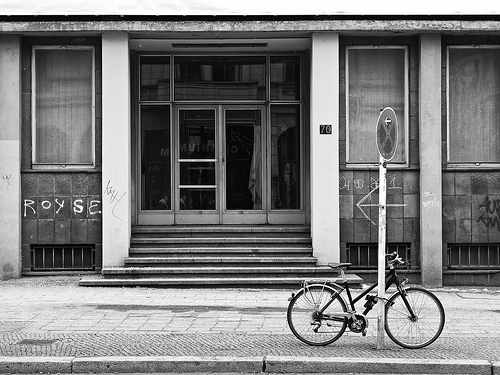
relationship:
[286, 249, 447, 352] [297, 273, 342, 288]
bike has cargo rack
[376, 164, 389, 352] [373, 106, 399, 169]
post has sign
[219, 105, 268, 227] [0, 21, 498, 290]
office door on building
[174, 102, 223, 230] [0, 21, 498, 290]
office door on building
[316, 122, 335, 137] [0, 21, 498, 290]
address numerals are on building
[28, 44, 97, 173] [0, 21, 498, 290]
window on building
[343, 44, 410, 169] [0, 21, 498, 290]
window on building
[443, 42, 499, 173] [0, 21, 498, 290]
window on building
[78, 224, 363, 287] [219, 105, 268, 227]
stairs are near office door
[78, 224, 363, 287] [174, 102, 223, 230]
stairs are near office door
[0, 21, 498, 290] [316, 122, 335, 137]
building has address numerals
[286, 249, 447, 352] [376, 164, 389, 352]
bike attached to post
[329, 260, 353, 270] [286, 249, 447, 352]
seat on bike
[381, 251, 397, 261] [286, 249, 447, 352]
handlebar on bike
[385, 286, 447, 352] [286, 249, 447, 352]
front wheel on bike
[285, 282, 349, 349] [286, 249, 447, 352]
back wheel on bike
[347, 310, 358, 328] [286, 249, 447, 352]
pedal on bike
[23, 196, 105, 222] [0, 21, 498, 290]
grafitti on building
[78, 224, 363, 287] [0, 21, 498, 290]
stairs are going up to building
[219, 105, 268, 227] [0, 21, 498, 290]
office door on front of building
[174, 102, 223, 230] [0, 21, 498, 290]
office door on front of building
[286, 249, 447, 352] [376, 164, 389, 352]
bike locked to post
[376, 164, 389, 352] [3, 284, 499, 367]
post on sidewalk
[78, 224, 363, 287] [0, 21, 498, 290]
stairs are in front of building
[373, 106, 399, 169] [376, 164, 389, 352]
sign on post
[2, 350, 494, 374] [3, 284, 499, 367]
curb on sidewalk